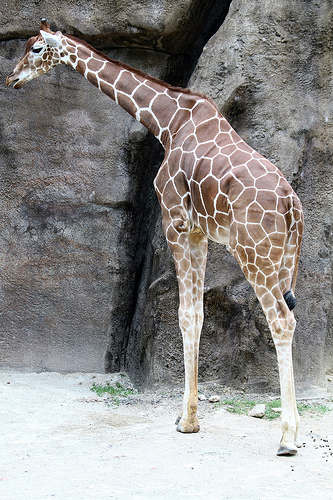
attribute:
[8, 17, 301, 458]
giraffe — sleepy, tall, brown, white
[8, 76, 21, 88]
mouth — open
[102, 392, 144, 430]
grass — sparse, green, small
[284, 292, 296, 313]
end — black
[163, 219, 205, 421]
leg — tall